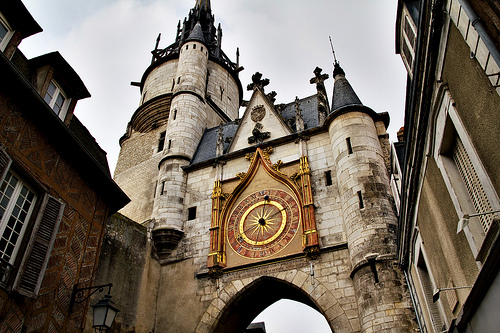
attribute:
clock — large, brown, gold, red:
[212, 148, 311, 269]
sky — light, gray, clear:
[246, 8, 337, 41]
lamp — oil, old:
[76, 276, 134, 332]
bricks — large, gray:
[334, 166, 380, 229]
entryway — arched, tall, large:
[192, 264, 350, 331]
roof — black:
[200, 124, 237, 144]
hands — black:
[256, 193, 287, 230]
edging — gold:
[294, 159, 332, 270]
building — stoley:
[1, 1, 138, 332]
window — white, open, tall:
[0, 142, 70, 302]